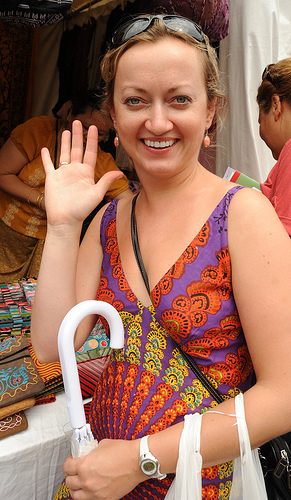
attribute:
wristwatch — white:
[140, 434, 168, 480]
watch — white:
[139, 433, 168, 480]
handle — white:
[56, 299, 125, 428]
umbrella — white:
[57, 298, 125, 457]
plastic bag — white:
[162, 392, 268, 498]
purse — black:
[131, 188, 287, 498]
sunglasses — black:
[109, 13, 210, 53]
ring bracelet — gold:
[24, 186, 45, 206]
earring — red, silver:
[112, 136, 120, 147]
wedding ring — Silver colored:
[57, 160, 69, 167]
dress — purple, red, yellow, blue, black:
[52, 183, 255, 499]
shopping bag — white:
[161, 392, 267, 498]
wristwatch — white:
[136, 429, 168, 481]